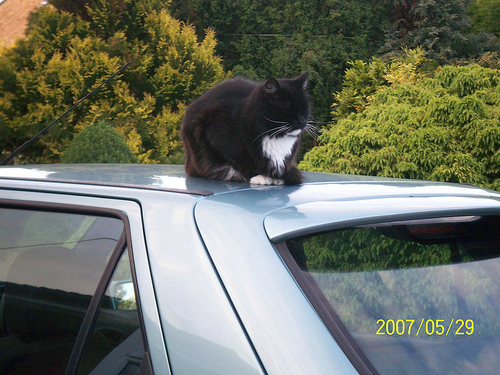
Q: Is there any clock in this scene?
A: No, there are no clocks.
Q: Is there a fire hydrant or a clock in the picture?
A: No, there are no clocks or fire hydrants.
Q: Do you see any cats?
A: Yes, there is a cat.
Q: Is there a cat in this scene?
A: Yes, there is a cat.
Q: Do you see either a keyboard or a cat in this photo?
A: Yes, there is a cat.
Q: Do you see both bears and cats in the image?
A: No, there is a cat but no bears.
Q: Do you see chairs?
A: No, there are no chairs.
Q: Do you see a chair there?
A: No, there are no chairs.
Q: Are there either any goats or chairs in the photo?
A: No, there are no chairs or goats.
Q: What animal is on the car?
A: The cat is on the car.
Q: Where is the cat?
A: The cat is on the car.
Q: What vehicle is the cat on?
A: The cat is on the car.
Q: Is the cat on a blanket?
A: No, the cat is on the car.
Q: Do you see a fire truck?
A: No, there are no fire trucks.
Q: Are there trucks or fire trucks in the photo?
A: No, there are no fire trucks or trucks.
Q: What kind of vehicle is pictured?
A: The vehicle is a car.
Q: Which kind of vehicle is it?
A: The vehicle is a car.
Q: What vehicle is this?
A: This is a car.